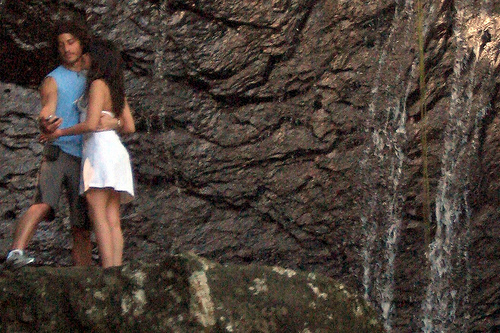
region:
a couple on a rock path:
[0, 8, 227, 298]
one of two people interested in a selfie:
[0, 17, 143, 331]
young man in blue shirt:
[0, 9, 150, 311]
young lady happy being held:
[0, 10, 145, 300]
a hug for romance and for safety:
[2, 6, 144, 317]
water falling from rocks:
[286, 4, 497, 319]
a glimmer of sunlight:
[353, 0, 498, 200]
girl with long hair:
[54, 22, 153, 281]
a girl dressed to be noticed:
[49, 22, 141, 291]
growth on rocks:
[226, 260, 355, 326]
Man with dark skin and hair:
[17, 20, 94, 274]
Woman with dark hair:
[75, 33, 138, 119]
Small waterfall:
[332, 19, 483, 282]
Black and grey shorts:
[22, 133, 95, 233]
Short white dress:
[60, 86, 150, 215]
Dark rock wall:
[163, 30, 349, 233]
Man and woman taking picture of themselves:
[10, 21, 162, 275]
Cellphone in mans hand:
[19, 105, 88, 157]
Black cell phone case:
[33, 139, 68, 172]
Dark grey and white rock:
[143, 252, 318, 325]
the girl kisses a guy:
[76, 52, 95, 68]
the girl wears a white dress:
[77, 91, 134, 198]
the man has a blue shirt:
[44, 65, 89, 155]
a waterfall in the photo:
[350, 0, 498, 327]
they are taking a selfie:
[41, 113, 61, 127]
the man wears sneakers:
[5, 250, 40, 265]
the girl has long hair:
[86, 42, 126, 117]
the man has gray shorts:
[30, 147, 92, 230]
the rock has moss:
[7, 252, 374, 329]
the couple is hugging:
[4, 27, 139, 277]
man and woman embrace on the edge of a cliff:
[3, 21, 144, 284]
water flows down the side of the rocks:
[406, 6, 453, 329]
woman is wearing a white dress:
[77, 110, 138, 196]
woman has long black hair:
[75, 32, 125, 117]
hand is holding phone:
[35, 111, 55, 127]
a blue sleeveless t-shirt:
[49, 68, 89, 160]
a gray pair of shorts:
[29, 144, 99, 221]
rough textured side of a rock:
[170, 15, 352, 274]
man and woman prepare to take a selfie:
[20, 23, 127, 264]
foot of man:
[3, 248, 38, 269]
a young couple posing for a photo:
[0, 25, 151, 280]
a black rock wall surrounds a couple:
[213, 39, 385, 244]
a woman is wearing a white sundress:
[83, 35, 148, 261]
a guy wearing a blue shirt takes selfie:
[9, 21, 96, 275]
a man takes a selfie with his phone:
[24, 23, 76, 145]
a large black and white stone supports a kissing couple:
[11, 256, 344, 327]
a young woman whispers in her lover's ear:
[84, 32, 146, 257]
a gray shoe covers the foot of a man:
[1, 243, 38, 271]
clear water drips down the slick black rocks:
[151, 30, 204, 249]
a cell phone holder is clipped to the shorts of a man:
[37, 144, 66, 168]